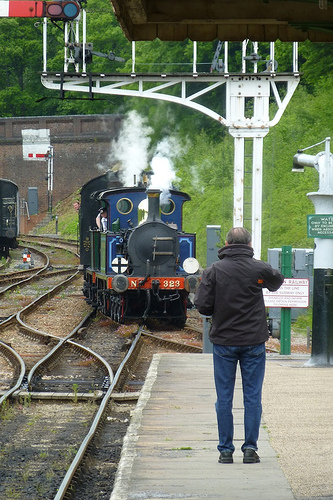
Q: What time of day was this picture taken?
A: Day time.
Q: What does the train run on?
A: Tracks.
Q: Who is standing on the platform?
A: The man.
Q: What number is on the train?
A: 323.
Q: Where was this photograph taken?
A: A train station.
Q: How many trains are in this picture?
A: Two.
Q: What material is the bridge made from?
A: Brick.